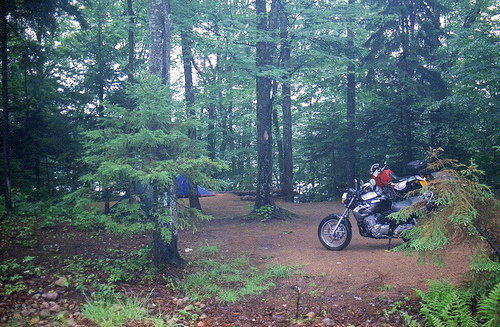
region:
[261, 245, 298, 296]
part of a ground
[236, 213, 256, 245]
part of a ground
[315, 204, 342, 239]
part fo a wheel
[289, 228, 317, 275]
part of a ground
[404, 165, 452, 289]
part of a plant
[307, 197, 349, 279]
part of a wheel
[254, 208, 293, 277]
part of a ground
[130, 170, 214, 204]
Blue tent in the woods.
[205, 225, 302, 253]
Patch of bare earth.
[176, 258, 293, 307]
Green grass on the ground.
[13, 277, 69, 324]
Rocks scattered in the forest.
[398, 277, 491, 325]
Beautiful bright green ferns.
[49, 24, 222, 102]
Sky through the trees.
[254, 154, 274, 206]
Moss growing on the trunk.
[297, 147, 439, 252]
Two motorcycles in the woods.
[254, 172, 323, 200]
A bit of lake showing.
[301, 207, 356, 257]
Front wheel of a motorcycle.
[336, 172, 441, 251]
the bike is black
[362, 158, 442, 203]
the bike is black and red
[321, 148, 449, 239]
the bikes are two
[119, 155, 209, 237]
the tents are two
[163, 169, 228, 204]
the tent is blue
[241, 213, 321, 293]
the ground i brown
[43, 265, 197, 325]
pebbles are on the ground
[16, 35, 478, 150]
the trees are few meters apart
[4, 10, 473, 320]
the scene is in the wild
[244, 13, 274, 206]
the etree bark is grey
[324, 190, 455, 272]
the bike is blackin color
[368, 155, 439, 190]
the bike is red and black in color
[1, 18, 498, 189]
the leaves are green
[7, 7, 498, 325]
the photo was taken inside the forest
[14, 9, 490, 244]
the trees are closely apart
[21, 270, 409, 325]
stones are on the ground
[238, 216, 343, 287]
the sand is brown in color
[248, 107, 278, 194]
the tree bar is grey in color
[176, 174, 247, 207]
tent is blue in color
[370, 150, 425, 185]
the bike is red and black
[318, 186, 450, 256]
the bike is black in color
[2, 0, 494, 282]
the tress are closely apart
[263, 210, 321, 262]
the ground is brown in color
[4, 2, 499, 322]
it is daytime in the scene